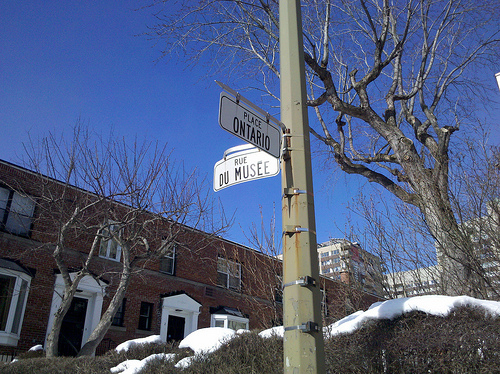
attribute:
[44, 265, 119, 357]
door — black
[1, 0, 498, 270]
skies — blue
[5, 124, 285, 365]
building — red, brick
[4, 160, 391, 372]
building — red, brick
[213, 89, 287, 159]
sign — white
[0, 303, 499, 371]
grass — dry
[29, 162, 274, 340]
building — brick, red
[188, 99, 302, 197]
sign — white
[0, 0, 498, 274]
sky — clear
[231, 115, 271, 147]
lettering — black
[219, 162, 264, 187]
lettering — black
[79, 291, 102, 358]
frame — white